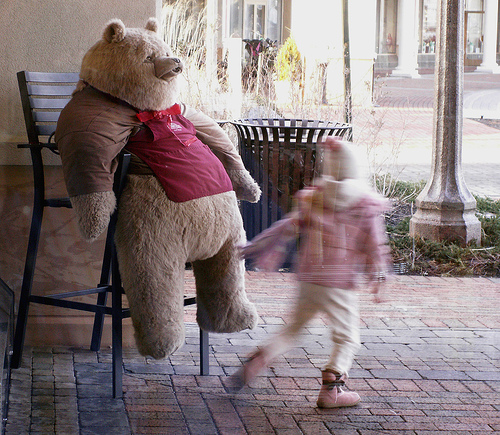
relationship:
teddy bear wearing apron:
[57, 17, 261, 357] [125, 109, 235, 202]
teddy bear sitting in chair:
[57, 17, 261, 357] [7, 69, 216, 399]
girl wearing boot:
[230, 135, 388, 408] [317, 368, 362, 407]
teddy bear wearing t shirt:
[57, 17, 261, 357] [55, 84, 248, 194]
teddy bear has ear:
[57, 17, 261, 357] [102, 18, 125, 44]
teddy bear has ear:
[57, 17, 261, 357] [146, 17, 158, 32]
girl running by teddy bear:
[230, 135, 388, 408] [57, 17, 261, 357]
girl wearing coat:
[230, 135, 388, 408] [258, 178, 388, 291]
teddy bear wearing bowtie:
[57, 17, 261, 357] [137, 104, 182, 122]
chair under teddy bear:
[7, 69, 216, 399] [57, 17, 261, 357]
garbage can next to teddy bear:
[228, 118, 352, 269] [57, 17, 261, 357]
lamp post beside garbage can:
[409, 2, 484, 246] [228, 118, 352, 269]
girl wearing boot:
[230, 135, 388, 408] [231, 352, 264, 389]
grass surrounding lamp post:
[379, 177, 500, 274] [409, 2, 484, 246]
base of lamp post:
[408, 217, 481, 246] [409, 2, 484, 246]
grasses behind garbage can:
[157, 1, 377, 148] [228, 118, 352, 269]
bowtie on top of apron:
[137, 104, 182, 122] [125, 109, 235, 202]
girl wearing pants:
[230, 135, 388, 408] [260, 283, 363, 379]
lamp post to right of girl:
[409, 2, 484, 246] [230, 135, 388, 408]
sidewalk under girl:
[0, 268, 498, 434] [230, 135, 388, 408]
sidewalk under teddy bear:
[0, 268, 498, 434] [57, 17, 261, 357]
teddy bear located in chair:
[57, 17, 261, 357] [7, 69, 216, 399]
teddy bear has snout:
[57, 17, 261, 357] [154, 57, 184, 83]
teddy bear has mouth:
[57, 17, 261, 357] [173, 66, 182, 74]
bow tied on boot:
[323, 378, 345, 389] [317, 368, 362, 407]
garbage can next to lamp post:
[228, 118, 352, 269] [409, 2, 484, 246]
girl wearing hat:
[230, 135, 388, 408] [324, 133, 363, 180]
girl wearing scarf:
[230, 135, 388, 408] [236, 215, 282, 261]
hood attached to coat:
[317, 178, 368, 213] [258, 178, 388, 291]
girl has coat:
[230, 135, 388, 408] [258, 178, 388, 291]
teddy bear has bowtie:
[57, 17, 261, 357] [137, 104, 182, 122]